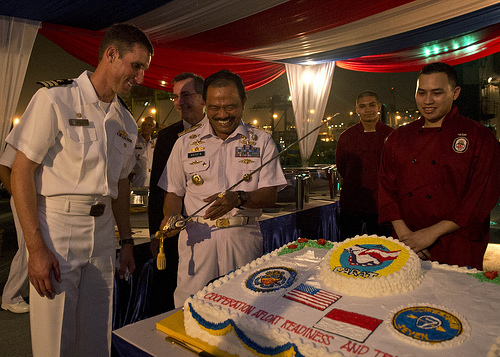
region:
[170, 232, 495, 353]
a cake on the table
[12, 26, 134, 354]
a man wearing a white shirt and pants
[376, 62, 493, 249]
a man wearing a red shirt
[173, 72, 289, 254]
a man in white laughing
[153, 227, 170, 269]
a tassle off the long stick the man is holding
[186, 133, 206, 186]
the mans badges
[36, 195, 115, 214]
a white belt on the man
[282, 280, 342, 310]
the american flag on the cake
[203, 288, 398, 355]
red writing on the cake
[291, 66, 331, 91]
two lights in the background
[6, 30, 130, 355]
Man wearing a white uniforms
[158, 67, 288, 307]
Man wearing a white uniform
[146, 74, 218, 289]
Man wearing a black suit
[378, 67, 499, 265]
Man wearing a red shirt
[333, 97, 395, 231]
Man wearing a red shirt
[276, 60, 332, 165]
Curtain in the background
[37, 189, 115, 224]
Belt around the man's waist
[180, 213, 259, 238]
Belt around the man's waist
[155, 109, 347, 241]
Sword in the man's hand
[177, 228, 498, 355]
Cake on the table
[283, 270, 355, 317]
an american flag made from icing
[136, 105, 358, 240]
a cermonial sword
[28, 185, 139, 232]
a white sailors belt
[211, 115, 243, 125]
a black mustache on a face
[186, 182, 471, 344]
a giant cake with decorations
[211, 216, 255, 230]
a golden belt buckle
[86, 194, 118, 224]
a golden belt buckle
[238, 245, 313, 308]
a united states navy logo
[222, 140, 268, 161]
button and awards on a shirt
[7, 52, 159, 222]
a white military uniform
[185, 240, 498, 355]
a giant cake with white frosting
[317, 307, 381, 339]
Indonesia flag on the cake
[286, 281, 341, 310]
United States flag on the cake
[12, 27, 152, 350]
US Navy captain in dress whites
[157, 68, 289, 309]
Indonesian Navy captain in white's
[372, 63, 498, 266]
the chef by the cake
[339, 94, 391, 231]
the sous chef behind the chef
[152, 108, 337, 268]
a gold sword with a yellow tassel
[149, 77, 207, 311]
man in a dark suit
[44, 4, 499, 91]
red and white fabric on the ceiling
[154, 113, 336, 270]
a man holding a sword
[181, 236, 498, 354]
a huge cake on a table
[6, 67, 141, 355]
man wearing a white navy uniform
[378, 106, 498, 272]
man wearing a red uniform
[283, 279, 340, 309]
an American flag on a cake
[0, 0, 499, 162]
white, red and blue drapes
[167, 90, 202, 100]
man wearing glasses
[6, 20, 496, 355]
men standing in front of a cake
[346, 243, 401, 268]
a handshake drawn on a cake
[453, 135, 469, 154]
a logo on man's uniform